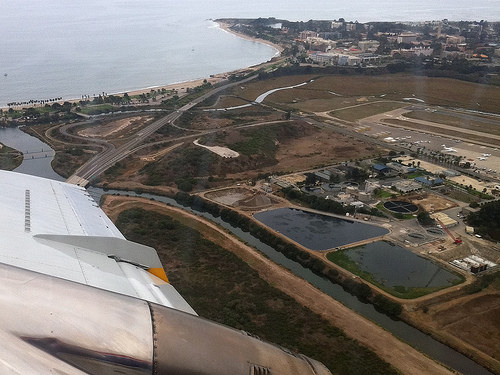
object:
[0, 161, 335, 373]
automobiles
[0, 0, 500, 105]
large water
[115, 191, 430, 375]
trees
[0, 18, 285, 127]
beach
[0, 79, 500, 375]
water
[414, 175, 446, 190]
building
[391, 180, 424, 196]
building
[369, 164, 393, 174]
building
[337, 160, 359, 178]
building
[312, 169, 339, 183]
building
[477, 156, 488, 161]
airplane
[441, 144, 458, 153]
airplane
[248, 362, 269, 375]
vent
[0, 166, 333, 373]
airplane wing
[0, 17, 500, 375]
land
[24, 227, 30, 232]
window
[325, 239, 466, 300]
pond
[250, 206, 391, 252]
pond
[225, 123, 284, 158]
trees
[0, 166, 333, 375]
plane side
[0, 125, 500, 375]
creek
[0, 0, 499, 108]
water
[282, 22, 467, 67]
buildings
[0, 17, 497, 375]
ground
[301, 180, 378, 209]
buildings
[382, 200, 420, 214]
landing pad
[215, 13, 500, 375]
city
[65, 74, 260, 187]
highway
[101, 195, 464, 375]
dirt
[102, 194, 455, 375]
path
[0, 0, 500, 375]
field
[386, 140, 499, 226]
trees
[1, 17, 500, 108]
shore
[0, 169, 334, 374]
airplane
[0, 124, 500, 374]
canal